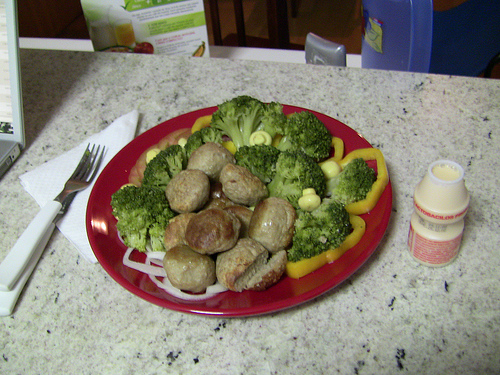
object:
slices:
[141, 256, 166, 291]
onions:
[121, 246, 166, 279]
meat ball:
[182, 203, 243, 256]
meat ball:
[160, 245, 216, 293]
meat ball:
[162, 210, 194, 252]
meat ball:
[162, 169, 211, 213]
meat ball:
[185, 141, 234, 178]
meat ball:
[216, 161, 270, 205]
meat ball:
[247, 193, 294, 253]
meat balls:
[213, 234, 290, 293]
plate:
[85, 101, 393, 318]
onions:
[156, 275, 219, 302]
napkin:
[16, 107, 138, 265]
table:
[0, 47, 499, 374]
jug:
[405, 158, 469, 269]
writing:
[407, 233, 462, 265]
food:
[334, 147, 389, 216]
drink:
[405, 159, 470, 268]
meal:
[86, 95, 392, 319]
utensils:
[0, 141, 108, 293]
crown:
[110, 183, 173, 218]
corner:
[6, 117, 29, 164]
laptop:
[0, 0, 28, 180]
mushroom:
[246, 128, 271, 148]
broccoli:
[109, 183, 170, 252]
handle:
[0, 199, 63, 292]